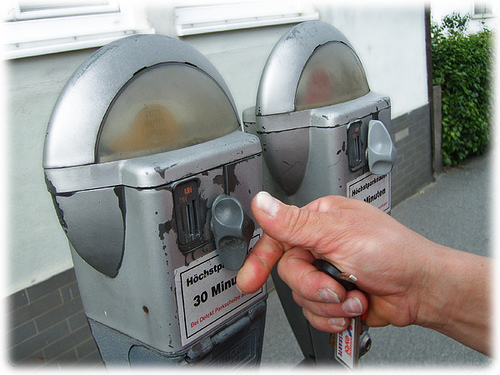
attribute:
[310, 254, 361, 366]
keys — rental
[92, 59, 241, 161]
meter window — yellow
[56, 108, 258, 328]
parking meter — silver , metal 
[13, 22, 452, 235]
building — painted , white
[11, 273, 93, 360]
foundation — brick 